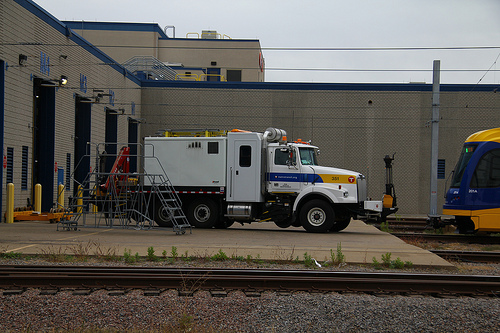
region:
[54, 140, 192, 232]
a movable stair case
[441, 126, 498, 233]
a blue and yellow train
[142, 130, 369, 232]
a white work truck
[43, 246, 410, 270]
weeds growing in the rocks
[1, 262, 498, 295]
a set of train tracks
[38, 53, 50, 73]
number on the building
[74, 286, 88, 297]
a wood board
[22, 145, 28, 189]
a vent on the wall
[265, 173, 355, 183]
an accent stripe on the truck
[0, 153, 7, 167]
a stop sign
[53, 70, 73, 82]
a light on the building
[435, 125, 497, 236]
a yellow and blue train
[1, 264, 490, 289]
the train tracks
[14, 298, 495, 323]
rocks next to the train tracks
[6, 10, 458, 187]
a building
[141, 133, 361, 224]
a white truck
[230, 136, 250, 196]
a door on the truck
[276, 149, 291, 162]
a window in the truck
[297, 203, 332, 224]
the tire on the truck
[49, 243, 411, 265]
weeds next to the train tracks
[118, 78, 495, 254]
a truck parked in front of a train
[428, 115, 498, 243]
the front of a train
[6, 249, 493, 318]
the rails of a train track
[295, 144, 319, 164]
the windshield of a truck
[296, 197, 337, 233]
the wheel of a truck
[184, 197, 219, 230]
the wheel of a truck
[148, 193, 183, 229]
the wheel of a truck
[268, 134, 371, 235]
the cab of a truck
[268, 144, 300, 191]
the passenger door of a truck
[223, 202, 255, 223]
the gas tank of a truck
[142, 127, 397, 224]
A truck by the train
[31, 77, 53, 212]
A grage door behind the truck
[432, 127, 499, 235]
A train on the tracks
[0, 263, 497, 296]
Tracks near the train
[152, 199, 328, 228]
Wheels on the truck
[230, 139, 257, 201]
A door on the truck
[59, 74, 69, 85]
A light connected to the building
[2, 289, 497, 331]
Gravel on the side of the tracks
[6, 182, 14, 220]
A yellow pole by the building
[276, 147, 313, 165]
Windows on the truck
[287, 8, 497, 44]
gray sky covered in clouds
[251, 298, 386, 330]
rocks alongside train tracks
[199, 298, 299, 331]
rocks to keep vegetation from growing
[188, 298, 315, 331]
rocks to facilitate water drainage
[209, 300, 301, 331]
rocks to help support weight on the tracks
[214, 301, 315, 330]
rock ballast laid next to, under and in between track ties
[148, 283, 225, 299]
track tie to help support weight of train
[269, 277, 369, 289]
rails for train to glide on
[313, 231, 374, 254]
slab of paved road for easier transfer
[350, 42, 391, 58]
power lines to help power trains and buildings